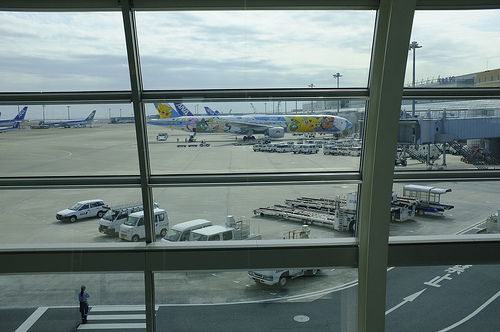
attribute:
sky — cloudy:
[2, 7, 499, 107]